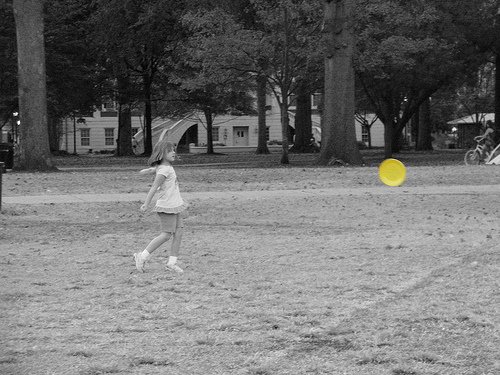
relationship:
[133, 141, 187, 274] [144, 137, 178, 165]
girl has hair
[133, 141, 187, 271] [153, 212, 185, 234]
girl wearing shorts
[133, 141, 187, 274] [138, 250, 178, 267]
girl has socks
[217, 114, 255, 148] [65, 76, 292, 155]
doors on building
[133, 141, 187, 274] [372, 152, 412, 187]
girl tossed disc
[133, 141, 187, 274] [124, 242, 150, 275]
girl in shoes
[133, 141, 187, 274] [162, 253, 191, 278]
girl in shoes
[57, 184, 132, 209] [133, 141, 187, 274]
grey path behind girl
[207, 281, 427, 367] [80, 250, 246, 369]
grass on ground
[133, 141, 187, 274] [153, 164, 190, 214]
girl wears shirt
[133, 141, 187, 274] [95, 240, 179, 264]
girl wears shoes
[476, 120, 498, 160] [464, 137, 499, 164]
person rides bike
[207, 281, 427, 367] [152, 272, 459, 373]
grass on playing area